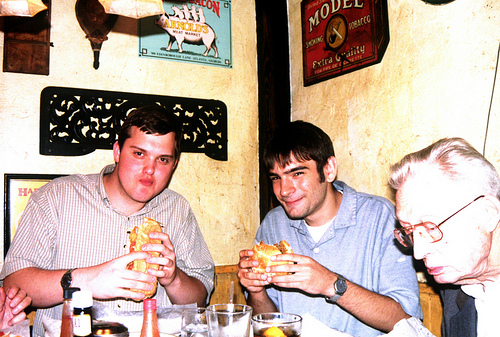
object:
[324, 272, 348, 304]
watch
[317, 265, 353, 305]
wrist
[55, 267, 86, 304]
wrist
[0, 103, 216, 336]
man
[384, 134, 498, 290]
man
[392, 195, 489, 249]
eyeglasses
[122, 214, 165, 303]
bread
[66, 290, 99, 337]
sauce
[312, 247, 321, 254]
button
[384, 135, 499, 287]
elderly man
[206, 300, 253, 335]
glass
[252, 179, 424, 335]
blue shirt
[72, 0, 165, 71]
light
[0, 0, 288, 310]
wall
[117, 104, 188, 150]
hair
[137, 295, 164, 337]
bottle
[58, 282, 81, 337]
bottle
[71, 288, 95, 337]
bottle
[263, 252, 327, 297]
hand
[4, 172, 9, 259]
black frame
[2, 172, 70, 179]
black frame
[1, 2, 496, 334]
picture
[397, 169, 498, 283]
man`s face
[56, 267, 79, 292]
watch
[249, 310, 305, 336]
glass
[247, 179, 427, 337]
shirt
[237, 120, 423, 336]
man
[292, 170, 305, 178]
eyes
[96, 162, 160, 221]
collar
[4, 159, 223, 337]
shirt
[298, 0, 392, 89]
poster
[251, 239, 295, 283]
sandwich